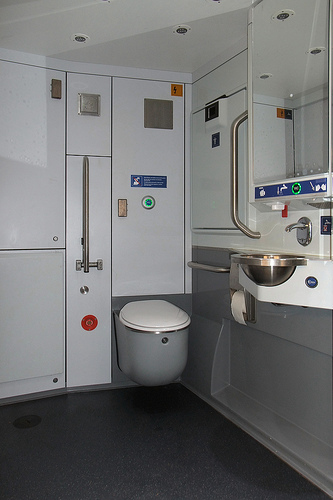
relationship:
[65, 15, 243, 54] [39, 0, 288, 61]
lights in ceiling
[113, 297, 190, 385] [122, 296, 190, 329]
toilet has lid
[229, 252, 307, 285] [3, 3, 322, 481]
sink in bathroom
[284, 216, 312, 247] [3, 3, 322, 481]
faucet in bathroom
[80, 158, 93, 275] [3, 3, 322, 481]
handle in bathroom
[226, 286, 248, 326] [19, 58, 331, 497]
toilet pape in bathroom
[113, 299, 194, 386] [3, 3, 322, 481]
toilet in bathroom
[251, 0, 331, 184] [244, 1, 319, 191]
mirror in bathroom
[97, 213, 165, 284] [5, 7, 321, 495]
wall on building